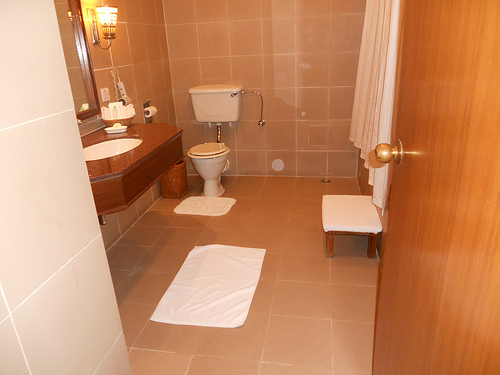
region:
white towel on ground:
[155, 243, 263, 319]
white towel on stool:
[329, 179, 382, 242]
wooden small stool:
[323, 190, 388, 268]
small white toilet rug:
[164, 182, 244, 213]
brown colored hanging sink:
[96, 128, 187, 186]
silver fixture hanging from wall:
[85, 9, 144, 55]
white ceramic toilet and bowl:
[180, 77, 251, 196]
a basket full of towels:
[95, 100, 143, 127]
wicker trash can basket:
[157, 156, 199, 209]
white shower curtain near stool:
[328, 53, 390, 189]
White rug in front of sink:
[149, 242, 271, 342]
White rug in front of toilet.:
[172, 193, 239, 218]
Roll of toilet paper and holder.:
[142, 97, 157, 124]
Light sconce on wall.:
[87, 3, 121, 54]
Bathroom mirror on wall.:
[52, 1, 101, 119]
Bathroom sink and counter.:
[74, 103, 184, 221]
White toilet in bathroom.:
[185, 79, 268, 198]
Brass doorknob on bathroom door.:
[369, 141, 411, 166]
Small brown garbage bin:
[158, 160, 190, 199]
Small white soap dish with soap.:
[105, 123, 125, 134]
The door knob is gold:
[369, 137, 406, 167]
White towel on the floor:
[158, 227, 268, 334]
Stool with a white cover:
[310, 181, 383, 258]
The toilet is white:
[178, 81, 255, 194]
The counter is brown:
[78, 112, 185, 226]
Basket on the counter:
[98, 99, 140, 129]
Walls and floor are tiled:
[18, 26, 360, 363]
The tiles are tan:
[24, 38, 378, 373]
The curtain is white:
[337, 22, 400, 214]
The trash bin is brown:
[160, 163, 192, 198]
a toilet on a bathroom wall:
[180, 83, 253, 193]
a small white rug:
[154, 243, 268, 327]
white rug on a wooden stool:
[318, 193, 379, 256]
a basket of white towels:
[101, 103, 136, 131]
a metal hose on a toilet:
[242, 89, 264, 128]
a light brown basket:
[161, 161, 186, 198]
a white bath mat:
[172, 194, 234, 215]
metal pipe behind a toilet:
[214, 123, 222, 142]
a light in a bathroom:
[87, 2, 118, 49]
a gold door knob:
[372, 140, 404, 164]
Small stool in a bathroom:
[321, 193, 383, 256]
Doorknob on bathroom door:
[375, 139, 403, 166]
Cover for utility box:
[271, 157, 283, 172]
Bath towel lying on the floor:
[150, 241, 267, 327]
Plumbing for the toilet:
[241, 88, 266, 127]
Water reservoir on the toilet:
[186, 84, 242, 123]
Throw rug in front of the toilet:
[175, 194, 236, 215]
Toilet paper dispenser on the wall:
[142, 100, 158, 123]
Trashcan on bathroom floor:
[157, 160, 186, 198]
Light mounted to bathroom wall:
[90, 5, 118, 47]